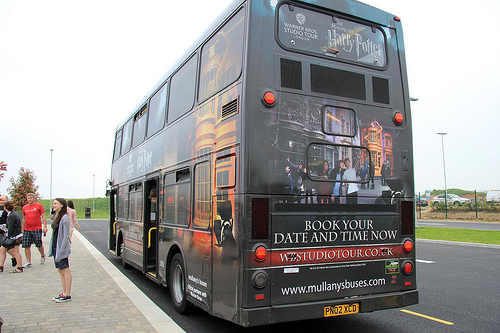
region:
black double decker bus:
[110, 0, 417, 327]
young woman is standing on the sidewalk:
[47, 200, 72, 300]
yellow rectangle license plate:
[323, 302, 360, 316]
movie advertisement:
[278, 2, 387, 69]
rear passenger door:
[145, 178, 156, 274]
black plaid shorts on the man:
[24, 230, 41, 249]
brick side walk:
[3, 224, 150, 330]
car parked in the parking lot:
[433, 191, 469, 205]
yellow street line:
[400, 308, 452, 326]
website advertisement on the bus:
[279, 278, 387, 295]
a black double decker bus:
[78, 0, 453, 327]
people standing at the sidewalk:
[10, 169, 90, 299]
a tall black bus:
[111, 15, 423, 328]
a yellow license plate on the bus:
[323, 303, 362, 313]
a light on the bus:
[254, 245, 266, 260]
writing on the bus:
[276, 39, 406, 286]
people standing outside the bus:
[9, 202, 99, 294]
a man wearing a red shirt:
[23, 193, 46, 260]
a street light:
[47, 150, 59, 210]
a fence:
[423, 188, 497, 212]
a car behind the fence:
[427, 193, 471, 202]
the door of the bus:
[143, 186, 156, 265]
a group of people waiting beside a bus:
[4, 0, 494, 327]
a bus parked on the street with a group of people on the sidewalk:
[1, 0, 496, 329]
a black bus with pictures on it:
[109, 0, 424, 328]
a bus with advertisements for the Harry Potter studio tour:
[106, 0, 426, 325]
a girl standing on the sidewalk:
[45, 192, 80, 302]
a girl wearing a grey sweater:
[0, 200, 29, 275]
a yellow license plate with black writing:
[319, 301, 365, 318]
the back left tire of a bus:
[156, 244, 197, 315]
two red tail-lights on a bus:
[392, 232, 418, 286]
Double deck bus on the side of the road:
[104, 0, 422, 324]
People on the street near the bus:
[0, 192, 81, 303]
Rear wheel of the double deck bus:
[166, 247, 199, 312]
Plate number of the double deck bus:
[323, 301, 361, 319]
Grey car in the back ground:
[431, 192, 476, 207]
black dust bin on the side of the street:
[83, 206, 93, 219]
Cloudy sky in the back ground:
[1, 0, 496, 197]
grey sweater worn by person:
[48, 211, 73, 263]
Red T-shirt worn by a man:
[21, 201, 46, 232]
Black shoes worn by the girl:
[51, 292, 74, 304]